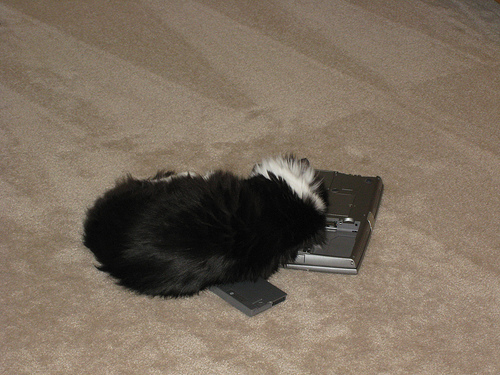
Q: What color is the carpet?
A: Tan.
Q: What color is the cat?
A: Black and white.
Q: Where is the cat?
A: On the floor.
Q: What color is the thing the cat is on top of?
A: Silver.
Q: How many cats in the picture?
A: 1.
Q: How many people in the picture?
A: Zero.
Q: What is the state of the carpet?
A: Freshly cleaned.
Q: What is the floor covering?
A: Carpet.